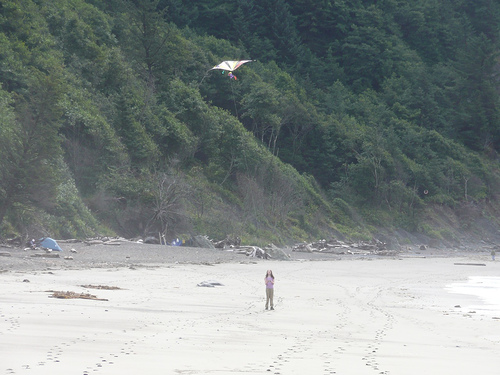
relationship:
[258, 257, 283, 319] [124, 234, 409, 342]
girl at beach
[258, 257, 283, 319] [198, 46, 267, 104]
girl flying kite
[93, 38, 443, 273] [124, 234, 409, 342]
trees at beach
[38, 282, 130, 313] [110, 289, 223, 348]
seaweeds on sand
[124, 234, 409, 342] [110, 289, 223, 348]
beach has sand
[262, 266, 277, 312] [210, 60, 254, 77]
girl flying kite